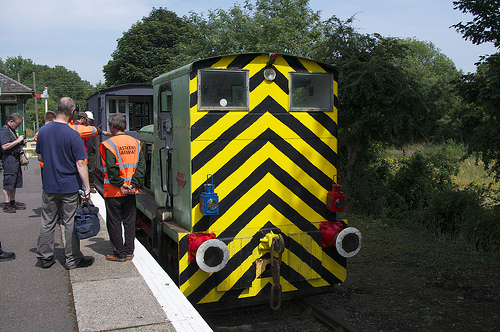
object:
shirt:
[35, 120, 88, 194]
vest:
[100, 133, 142, 198]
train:
[74, 51, 366, 313]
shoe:
[65, 255, 96, 270]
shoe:
[37, 255, 57, 268]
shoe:
[0, 250, 17, 262]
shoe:
[3, 205, 17, 213]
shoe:
[10, 204, 26, 211]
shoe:
[105, 254, 126, 263]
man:
[100, 113, 147, 261]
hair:
[108, 113, 128, 132]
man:
[0, 110, 31, 214]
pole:
[32, 72, 39, 133]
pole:
[16, 72, 27, 139]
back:
[175, 52, 362, 305]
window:
[196, 68, 250, 111]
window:
[289, 72, 334, 112]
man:
[35, 95, 96, 270]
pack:
[73, 191, 101, 240]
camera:
[19, 129, 27, 148]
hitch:
[257, 231, 286, 311]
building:
[1, 71, 35, 148]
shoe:
[126, 254, 135, 261]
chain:
[270, 238, 283, 310]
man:
[72, 112, 89, 172]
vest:
[66, 123, 98, 149]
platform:
[2, 157, 216, 332]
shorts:
[1, 155, 23, 191]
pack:
[19, 148, 29, 170]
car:
[83, 83, 154, 186]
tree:
[101, 6, 193, 89]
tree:
[166, 0, 322, 71]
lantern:
[200, 174, 219, 217]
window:
[108, 99, 116, 114]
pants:
[104, 193, 138, 259]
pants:
[35, 190, 83, 271]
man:
[83, 110, 97, 194]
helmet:
[84, 110, 95, 120]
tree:
[338, 36, 465, 147]